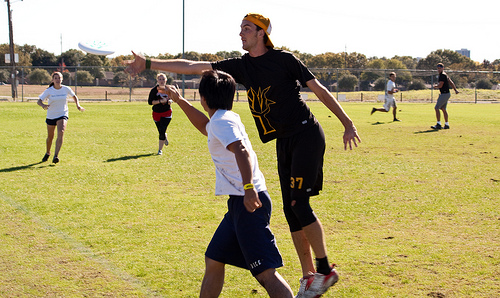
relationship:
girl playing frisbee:
[39, 72, 79, 159] [81, 40, 116, 69]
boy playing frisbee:
[158, 67, 296, 297] [81, 40, 116, 69]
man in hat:
[371, 73, 403, 119] [244, 10, 278, 49]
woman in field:
[39, 72, 79, 159] [3, 99, 499, 280]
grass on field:
[3, 99, 499, 280] [3, 99, 499, 280]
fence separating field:
[5, 59, 499, 121] [3, 99, 499, 280]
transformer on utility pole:
[3, 49, 22, 66] [2, 0, 19, 100]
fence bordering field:
[5, 59, 499, 121] [3, 99, 499, 280]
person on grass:
[366, 69, 399, 122] [3, 99, 499, 280]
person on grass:
[424, 59, 462, 133] [3, 99, 499, 280]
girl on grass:
[36, 72, 84, 165] [3, 99, 499, 280]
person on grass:
[147, 72, 173, 154] [3, 99, 499, 280]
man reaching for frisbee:
[120, 10, 360, 295] [81, 40, 116, 69]